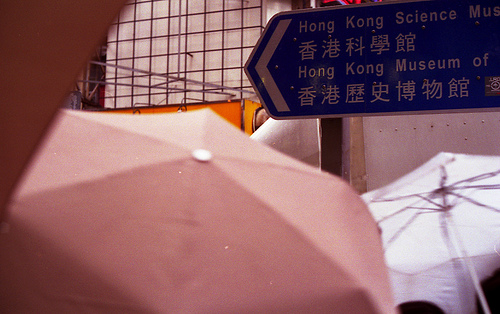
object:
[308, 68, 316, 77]
letter o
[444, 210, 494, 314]
handle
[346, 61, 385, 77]
kong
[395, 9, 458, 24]
foreign language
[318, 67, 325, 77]
letters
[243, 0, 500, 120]
sign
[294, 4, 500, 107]
writing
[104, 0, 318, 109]
wall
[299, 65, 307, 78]
letter h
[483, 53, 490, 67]
letter f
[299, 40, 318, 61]
chinese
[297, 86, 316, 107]
chinese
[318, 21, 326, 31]
white letter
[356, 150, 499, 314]
umbrella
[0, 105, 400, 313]
umbrella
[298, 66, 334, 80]
word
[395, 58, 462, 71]
word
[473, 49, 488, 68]
word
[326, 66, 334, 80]
g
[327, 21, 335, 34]
g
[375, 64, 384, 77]
g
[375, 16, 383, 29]
g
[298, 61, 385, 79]
hong kong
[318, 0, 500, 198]
wall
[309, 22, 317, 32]
character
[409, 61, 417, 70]
character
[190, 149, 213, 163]
button